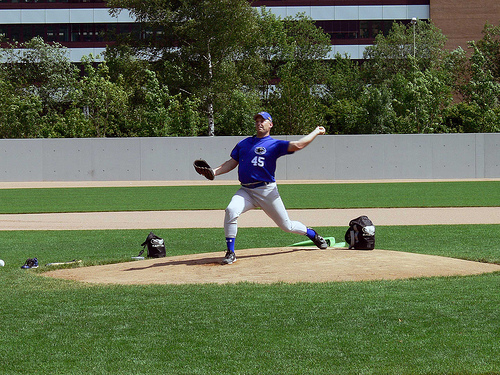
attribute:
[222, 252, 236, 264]
shoe — black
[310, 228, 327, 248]
shoe — black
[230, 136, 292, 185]
jersey — blue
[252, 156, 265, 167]
number — 45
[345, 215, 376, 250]
bag — black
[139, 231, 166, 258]
bag — black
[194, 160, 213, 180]
mitt — brown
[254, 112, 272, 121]
hat — blue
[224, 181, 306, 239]
pants — white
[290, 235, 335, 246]
plate — green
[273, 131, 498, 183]
wall — tall